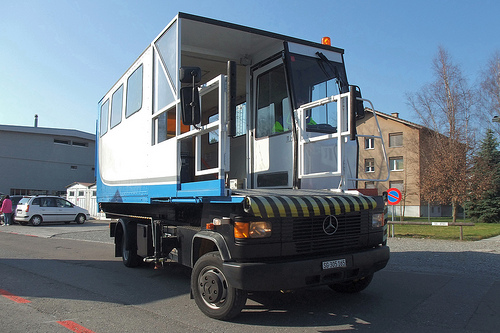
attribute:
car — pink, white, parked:
[12, 192, 100, 225]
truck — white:
[76, 31, 402, 326]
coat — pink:
[3, 200, 12, 212]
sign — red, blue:
[388, 185, 406, 235]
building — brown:
[348, 95, 477, 231]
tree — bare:
[402, 40, 490, 240]